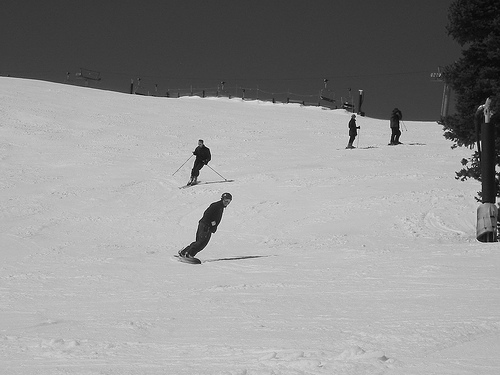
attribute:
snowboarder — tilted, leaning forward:
[178, 192, 233, 262]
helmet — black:
[221, 190, 232, 197]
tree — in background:
[440, 5, 499, 204]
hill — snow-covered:
[1, 79, 499, 375]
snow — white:
[4, 81, 182, 375]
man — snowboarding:
[179, 192, 235, 265]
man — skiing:
[168, 141, 232, 189]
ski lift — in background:
[69, 65, 176, 95]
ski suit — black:
[345, 121, 358, 146]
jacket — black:
[348, 117, 358, 135]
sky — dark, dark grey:
[1, 3, 453, 114]